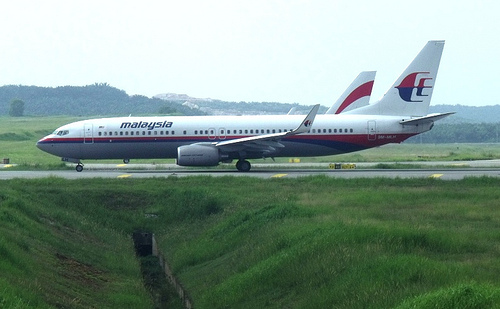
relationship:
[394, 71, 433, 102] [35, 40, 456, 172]
logo on aircraft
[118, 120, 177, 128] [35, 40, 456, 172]
logo on aircraft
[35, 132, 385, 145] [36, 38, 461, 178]
stripes on plane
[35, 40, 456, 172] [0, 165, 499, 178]
aircraft on runway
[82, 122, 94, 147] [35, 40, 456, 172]
door on aircraft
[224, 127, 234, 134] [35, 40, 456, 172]
window on aircraft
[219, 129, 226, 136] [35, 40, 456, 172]
window on aircraft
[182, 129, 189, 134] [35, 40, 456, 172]
window on aircraft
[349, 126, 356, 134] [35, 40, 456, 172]
window on aircraft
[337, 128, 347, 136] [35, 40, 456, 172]
window on aircraft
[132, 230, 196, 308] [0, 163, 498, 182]
ditch on runway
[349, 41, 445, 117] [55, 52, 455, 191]
tail of aircraft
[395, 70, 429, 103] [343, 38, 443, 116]
logo on tail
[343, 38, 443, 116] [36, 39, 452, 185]
tail of aircraft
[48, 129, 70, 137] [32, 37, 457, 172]
cockpit glass on aircraft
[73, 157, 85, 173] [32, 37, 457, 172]
landing gear of aircraft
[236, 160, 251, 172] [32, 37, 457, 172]
landing gear of aircraft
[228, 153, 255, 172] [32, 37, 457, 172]
landing gear of aircraft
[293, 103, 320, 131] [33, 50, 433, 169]
wingtip of aircraft